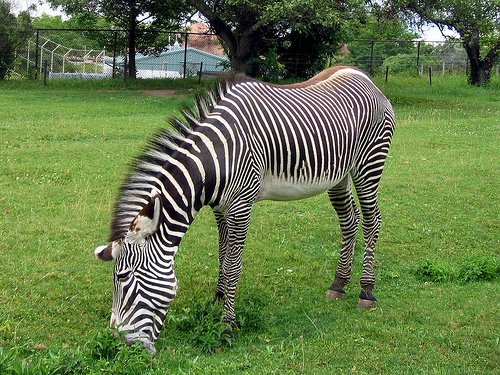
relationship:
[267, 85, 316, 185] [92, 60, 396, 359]
stripe on zebra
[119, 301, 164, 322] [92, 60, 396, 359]
stripe on zebra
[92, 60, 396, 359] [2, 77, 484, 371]
zebra standing in field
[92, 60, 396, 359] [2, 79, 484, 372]
zebra eating grass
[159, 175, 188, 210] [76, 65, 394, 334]
black stripe on zebra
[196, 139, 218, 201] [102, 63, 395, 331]
black stripe on zebra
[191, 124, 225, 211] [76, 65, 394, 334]
black stripe on zebra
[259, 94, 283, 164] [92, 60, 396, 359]
black stripe on zebra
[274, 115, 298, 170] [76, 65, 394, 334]
black stripe on zebra